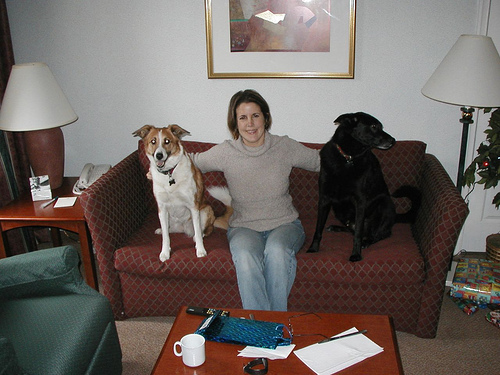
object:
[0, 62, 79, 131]
lamp shade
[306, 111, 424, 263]
dog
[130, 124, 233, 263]
dog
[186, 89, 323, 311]
woman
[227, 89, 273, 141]
hair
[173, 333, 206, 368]
coffee mug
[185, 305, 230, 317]
remote control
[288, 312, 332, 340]
eyeglasses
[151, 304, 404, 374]
table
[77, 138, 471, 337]
couch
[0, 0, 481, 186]
wall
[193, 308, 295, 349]
gift bag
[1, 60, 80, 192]
lamp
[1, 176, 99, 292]
side table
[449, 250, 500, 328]
gift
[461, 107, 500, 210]
tree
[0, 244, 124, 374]
recliner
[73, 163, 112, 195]
telephone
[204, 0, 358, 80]
frame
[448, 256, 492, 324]
gift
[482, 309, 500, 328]
gift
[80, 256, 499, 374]
floor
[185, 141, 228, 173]
arm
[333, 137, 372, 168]
neck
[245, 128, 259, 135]
smile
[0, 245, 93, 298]
arm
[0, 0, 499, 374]
living room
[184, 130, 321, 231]
sweater